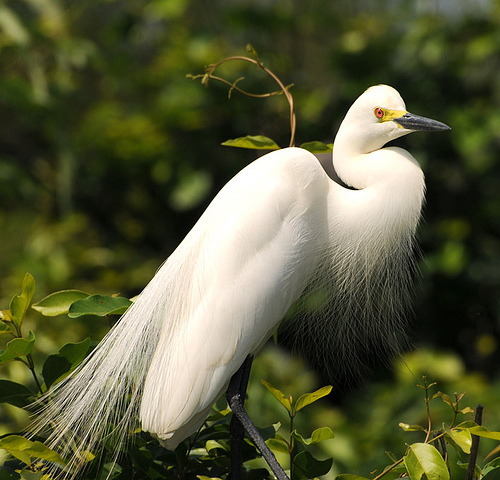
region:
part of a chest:
[254, 233, 296, 313]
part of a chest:
[260, 188, 343, 333]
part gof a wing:
[146, 206, 274, 348]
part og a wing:
[228, 259, 267, 342]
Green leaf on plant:
[402, 443, 449, 479]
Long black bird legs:
[225, 355, 289, 478]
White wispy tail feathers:
[21, 247, 185, 478]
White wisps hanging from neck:
[282, 211, 419, 388]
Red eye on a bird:
[374, 107, 384, 117]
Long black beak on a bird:
[397, 114, 452, 131]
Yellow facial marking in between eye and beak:
[381, 109, 405, 119]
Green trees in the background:
[0, 1, 498, 416]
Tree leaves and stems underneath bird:
[1, 272, 498, 479]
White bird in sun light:
[24, 84, 451, 479]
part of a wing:
[230, 310, 257, 355]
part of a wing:
[211, 304, 247, 352]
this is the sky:
[445, 3, 470, 28]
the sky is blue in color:
[440, 4, 458, 20]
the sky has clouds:
[441, 5, 464, 25]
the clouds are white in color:
[446, 2, 465, 18]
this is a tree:
[36, 38, 143, 178]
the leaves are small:
[80, 15, 186, 130]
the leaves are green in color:
[115, 61, 172, 120]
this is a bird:
[81, 77, 443, 474]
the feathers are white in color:
[186, 318, 239, 352]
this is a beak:
[396, 105, 451, 137]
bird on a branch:
[37, 61, 434, 439]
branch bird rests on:
[220, 396, 292, 471]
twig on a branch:
[265, 368, 335, 445]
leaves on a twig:
[258, 378, 319, 410]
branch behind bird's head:
[197, 40, 309, 147]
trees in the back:
[6, 6, 491, 156]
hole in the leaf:
[304, 390, 321, 400]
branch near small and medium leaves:
[466, 393, 491, 479]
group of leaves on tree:
[78, 105, 166, 160]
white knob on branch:
[231, 391, 240, 406]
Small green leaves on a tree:
[33, 275, 103, 331]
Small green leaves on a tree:
[272, 374, 337, 423]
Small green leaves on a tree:
[396, 432, 435, 478]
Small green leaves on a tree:
[285, 424, 312, 471]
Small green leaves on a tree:
[223, 124, 300, 149]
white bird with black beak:
[43, 75, 454, 470]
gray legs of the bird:
[218, 373, 299, 479]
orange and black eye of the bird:
[372, 106, 383, 120]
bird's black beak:
[402, 109, 447, 131]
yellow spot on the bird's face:
[385, 111, 405, 122]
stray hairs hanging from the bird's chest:
[311, 251, 405, 354]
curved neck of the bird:
[318, 140, 423, 254]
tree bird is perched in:
[7, 288, 485, 479]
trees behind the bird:
[8, 10, 498, 375]